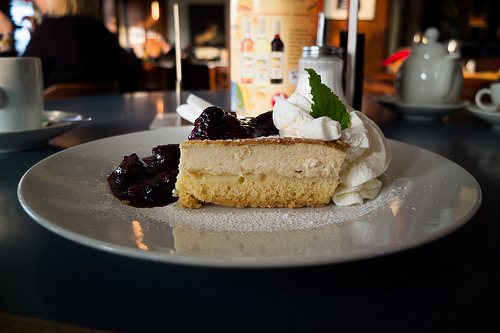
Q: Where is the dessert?
A: On the white plate.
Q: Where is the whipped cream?
A: On the dessert.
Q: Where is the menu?
A: Behind the plate.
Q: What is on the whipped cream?
A: A mint leaf.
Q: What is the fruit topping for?
A: The cake.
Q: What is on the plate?
A: A piece of white cake.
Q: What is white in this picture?
A: The china plate.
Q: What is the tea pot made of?
A: White china.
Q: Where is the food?
A: On the white plate.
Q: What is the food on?
A: Plate.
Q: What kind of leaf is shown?
A: Mint.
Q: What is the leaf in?
A: Whipped cream.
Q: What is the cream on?
A: Pie.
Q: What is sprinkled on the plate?
A: Sugar.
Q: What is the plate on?
A: Table.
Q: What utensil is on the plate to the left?
A: Spoon.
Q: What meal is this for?
A: Dessert.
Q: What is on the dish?
A: A slice of cake.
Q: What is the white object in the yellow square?
A: A teapot.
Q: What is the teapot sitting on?
A: A plate.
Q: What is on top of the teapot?
A: A lid.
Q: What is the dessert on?
A: A white plate.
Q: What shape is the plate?
A: Round.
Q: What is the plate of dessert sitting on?
A: A table.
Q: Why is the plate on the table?
A: It is being used.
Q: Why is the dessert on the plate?
A: To be eaten.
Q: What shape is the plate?
A: Circular.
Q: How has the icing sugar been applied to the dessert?
A: Sifted over it.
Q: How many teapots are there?
A: One.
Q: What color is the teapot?
A: White.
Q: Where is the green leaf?
A: In the cream.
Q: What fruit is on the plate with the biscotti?
A: Cherries.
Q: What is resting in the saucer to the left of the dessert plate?
A: A spoon.